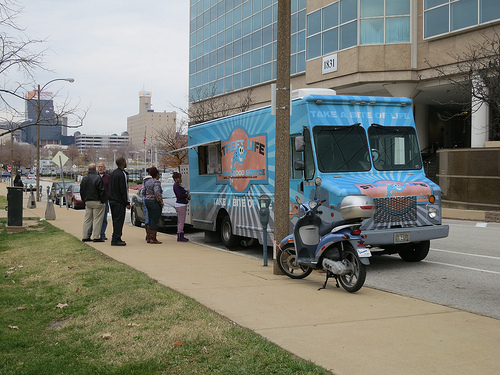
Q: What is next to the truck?
A: A scooter.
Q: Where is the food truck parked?
A: At the curb.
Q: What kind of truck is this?
A: A food truck.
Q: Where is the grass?
A: Beside the sidewalk.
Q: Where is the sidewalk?
A: Between the food truck and the grass.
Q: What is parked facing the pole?
A: A motorcycle.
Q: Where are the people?
A: Standing in line.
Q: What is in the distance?
A: Tall buildings.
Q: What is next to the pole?
A: Bike.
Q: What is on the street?
A: Food cart.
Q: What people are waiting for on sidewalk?
A: Food.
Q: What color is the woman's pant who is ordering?
A: Pink.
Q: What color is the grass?
A: Green.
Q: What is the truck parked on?
A: The street.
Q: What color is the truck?
A: Blue.